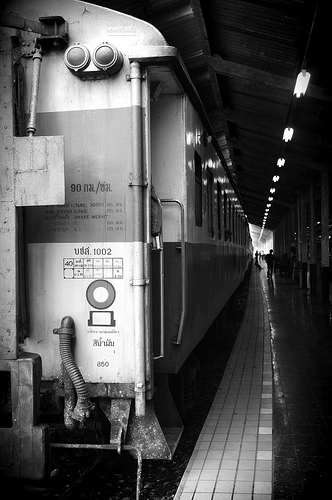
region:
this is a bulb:
[289, 66, 318, 104]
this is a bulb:
[276, 118, 298, 147]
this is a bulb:
[272, 147, 297, 176]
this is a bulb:
[269, 187, 279, 192]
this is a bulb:
[264, 203, 275, 208]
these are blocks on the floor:
[217, 454, 235, 486]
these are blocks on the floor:
[255, 447, 273, 472]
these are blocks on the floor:
[181, 468, 200, 494]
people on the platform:
[256, 239, 289, 276]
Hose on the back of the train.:
[41, 311, 107, 432]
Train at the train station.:
[92, 106, 262, 314]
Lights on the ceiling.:
[273, 95, 296, 191]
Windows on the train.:
[195, 165, 266, 232]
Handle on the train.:
[151, 185, 181, 350]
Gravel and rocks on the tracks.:
[104, 458, 181, 497]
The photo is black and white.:
[56, 26, 294, 489]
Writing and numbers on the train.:
[24, 179, 130, 243]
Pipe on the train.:
[30, 44, 48, 139]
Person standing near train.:
[262, 245, 277, 282]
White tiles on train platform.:
[216, 409, 249, 480]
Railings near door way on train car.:
[170, 202, 183, 369]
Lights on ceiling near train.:
[267, 114, 285, 253]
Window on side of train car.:
[203, 170, 215, 234]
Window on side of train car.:
[232, 205, 236, 243]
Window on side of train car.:
[238, 226, 243, 249]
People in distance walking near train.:
[256, 248, 260, 258]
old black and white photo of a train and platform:
[19, 14, 311, 470]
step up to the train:
[130, 386, 188, 461]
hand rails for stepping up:
[148, 192, 189, 363]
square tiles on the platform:
[194, 438, 267, 481]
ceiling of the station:
[189, 0, 323, 64]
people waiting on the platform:
[252, 242, 299, 279]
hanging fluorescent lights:
[269, 61, 306, 191]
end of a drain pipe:
[126, 222, 146, 416]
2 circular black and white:
[61, 31, 125, 73]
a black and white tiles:
[207, 362, 254, 477]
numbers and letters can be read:
[70, 237, 126, 279]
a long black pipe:
[44, 317, 100, 435]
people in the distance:
[245, 236, 294, 287]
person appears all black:
[260, 242, 286, 278]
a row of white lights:
[251, 151, 292, 262]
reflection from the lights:
[174, 127, 259, 217]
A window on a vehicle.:
[192, 150, 202, 227]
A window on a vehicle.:
[206, 166, 214, 238]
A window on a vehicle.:
[217, 180, 222, 239]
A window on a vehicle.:
[232, 206, 235, 243]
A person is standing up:
[254, 250, 258, 264]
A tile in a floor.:
[218, 458, 238, 470]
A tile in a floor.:
[253, 480, 273, 493]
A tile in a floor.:
[259, 407, 272, 415]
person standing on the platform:
[259, 239, 277, 279]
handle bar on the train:
[152, 185, 188, 375]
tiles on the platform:
[171, 332, 302, 498]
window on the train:
[189, 145, 206, 227]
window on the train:
[203, 163, 216, 242]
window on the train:
[228, 198, 235, 245]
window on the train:
[205, 162, 214, 235]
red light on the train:
[58, 38, 121, 75]